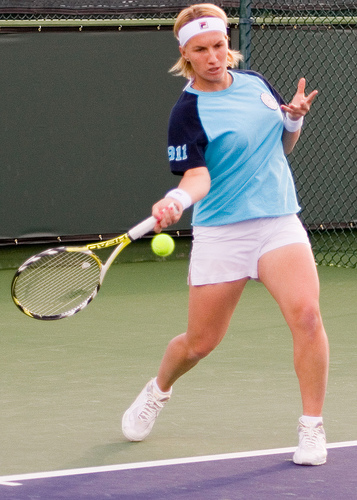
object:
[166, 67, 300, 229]
shirt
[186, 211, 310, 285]
tennis skirt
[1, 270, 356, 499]
floor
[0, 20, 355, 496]
court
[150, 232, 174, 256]
ball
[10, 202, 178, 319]
racquet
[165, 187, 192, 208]
wristband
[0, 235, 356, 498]
ground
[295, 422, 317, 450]
white laces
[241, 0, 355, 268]
fence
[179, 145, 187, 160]
numbers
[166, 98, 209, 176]
shirt sleeve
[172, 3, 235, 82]
head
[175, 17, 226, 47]
headband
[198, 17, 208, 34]
logo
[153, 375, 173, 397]
socks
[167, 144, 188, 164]
911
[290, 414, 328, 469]
shoe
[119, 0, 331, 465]
player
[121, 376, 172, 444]
shoe